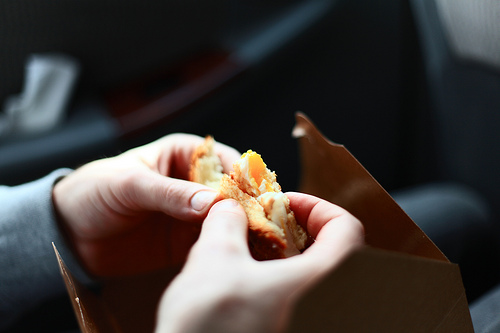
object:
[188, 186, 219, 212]
thum nail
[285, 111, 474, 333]
box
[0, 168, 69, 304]
wrist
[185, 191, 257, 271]
thumb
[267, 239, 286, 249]
seed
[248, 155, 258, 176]
cheese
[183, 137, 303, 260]
food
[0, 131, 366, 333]
person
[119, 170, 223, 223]
thumb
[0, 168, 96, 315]
jacket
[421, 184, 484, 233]
blue jeans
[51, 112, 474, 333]
bag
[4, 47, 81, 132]
cloth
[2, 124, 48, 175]
box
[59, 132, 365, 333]
hand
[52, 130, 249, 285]
left hand